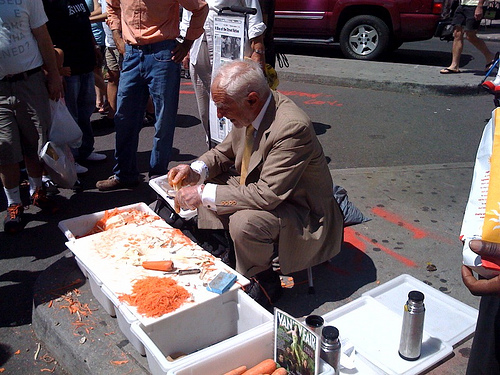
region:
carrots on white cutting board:
[69, 177, 256, 353]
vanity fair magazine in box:
[274, 263, 325, 373]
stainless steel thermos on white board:
[346, 249, 488, 374]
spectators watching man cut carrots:
[6, 1, 193, 236]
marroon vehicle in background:
[283, 1, 444, 102]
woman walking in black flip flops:
[417, 13, 494, 90]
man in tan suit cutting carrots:
[139, 59, 379, 355]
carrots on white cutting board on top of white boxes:
[89, 203, 183, 362]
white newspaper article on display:
[203, 13, 259, 264]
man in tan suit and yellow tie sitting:
[153, 67, 320, 319]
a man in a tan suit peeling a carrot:
[156, 52, 352, 317]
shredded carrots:
[104, 271, 204, 322]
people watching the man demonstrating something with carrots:
[1, 0, 366, 327]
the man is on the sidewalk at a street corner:
[19, 51, 478, 373]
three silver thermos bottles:
[302, 271, 432, 373]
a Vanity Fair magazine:
[270, 302, 322, 372]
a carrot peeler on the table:
[152, 262, 204, 282]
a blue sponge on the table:
[201, 259, 238, 314]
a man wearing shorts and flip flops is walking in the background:
[426, 4, 499, 94]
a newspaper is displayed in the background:
[201, 4, 283, 157]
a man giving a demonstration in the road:
[39, 54, 469, 367]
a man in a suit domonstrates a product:
[176, 59, 346, 300]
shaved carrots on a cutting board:
[87, 203, 235, 325]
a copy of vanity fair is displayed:
[265, 303, 333, 373]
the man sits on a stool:
[176, 64, 358, 310]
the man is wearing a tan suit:
[181, 51, 368, 288]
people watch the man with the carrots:
[3, 5, 188, 218]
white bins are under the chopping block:
[70, 196, 275, 371]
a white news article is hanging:
[208, 8, 247, 154]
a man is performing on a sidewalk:
[34, 37, 448, 367]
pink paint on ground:
[367, 200, 429, 245]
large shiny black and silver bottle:
[401, 293, 425, 373]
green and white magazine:
[252, 309, 337, 373]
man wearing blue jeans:
[100, 40, 190, 137]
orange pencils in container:
[239, 349, 278, 372]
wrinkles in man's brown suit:
[265, 144, 311, 181]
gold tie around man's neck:
[212, 128, 289, 202]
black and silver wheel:
[344, 13, 399, 82]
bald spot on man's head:
[205, 36, 257, 86]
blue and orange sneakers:
[1, 196, 43, 243]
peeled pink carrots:
[157, 286, 177, 298]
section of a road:
[390, 112, 413, 127]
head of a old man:
[231, 82, 259, 102]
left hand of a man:
[183, 190, 193, 204]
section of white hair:
[236, 72, 258, 84]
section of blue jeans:
[162, 61, 174, 116]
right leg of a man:
[453, 36, 466, 66]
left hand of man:
[38, 17, 52, 58]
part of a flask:
[405, 305, 420, 357]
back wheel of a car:
[346, 22, 385, 50]